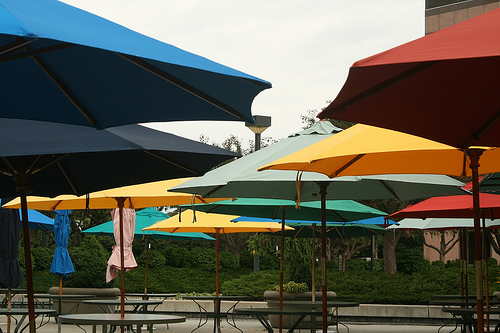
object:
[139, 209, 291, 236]
umbrella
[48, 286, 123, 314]
cement planter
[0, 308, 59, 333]
tables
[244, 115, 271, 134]
light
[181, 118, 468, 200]
umbrella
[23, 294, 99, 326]
table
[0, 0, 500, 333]
background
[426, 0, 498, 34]
building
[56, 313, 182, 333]
tables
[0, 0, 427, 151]
cloudy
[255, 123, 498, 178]
umbrellas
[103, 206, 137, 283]
umbrella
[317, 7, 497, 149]
umbrellas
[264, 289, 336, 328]
pot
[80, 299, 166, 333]
table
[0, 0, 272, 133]
umbrellas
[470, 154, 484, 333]
pole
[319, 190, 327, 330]
pole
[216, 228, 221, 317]
pole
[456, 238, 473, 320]
pole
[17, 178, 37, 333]
pole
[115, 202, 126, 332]
pole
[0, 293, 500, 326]
wall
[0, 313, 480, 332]
patio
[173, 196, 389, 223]
umbrella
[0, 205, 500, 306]
bushes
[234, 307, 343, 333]
tables